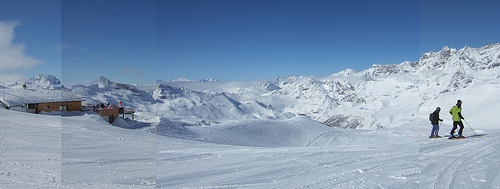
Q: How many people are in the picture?
A: 2.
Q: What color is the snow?
A: White.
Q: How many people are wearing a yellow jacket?
A: One.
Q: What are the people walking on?
A: Snow.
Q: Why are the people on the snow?
A: Skiing.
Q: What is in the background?
A: Snow covered mountains.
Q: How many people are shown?
A: 2.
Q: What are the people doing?
A: Skiing.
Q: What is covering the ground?
A: Snow.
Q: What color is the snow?
A: White.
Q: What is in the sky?
A: Cloud.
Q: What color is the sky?
A: Blue.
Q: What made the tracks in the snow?
A: Skis.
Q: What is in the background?
A: Mountains.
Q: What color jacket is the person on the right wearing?
A: Yellow.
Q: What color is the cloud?
A: White.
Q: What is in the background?
A: Mountains.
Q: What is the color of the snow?
A: White.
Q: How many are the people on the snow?
A: Two.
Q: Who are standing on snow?
A: Two people.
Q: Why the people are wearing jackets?
A: It's winter.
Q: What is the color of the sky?
A: Blue and white.